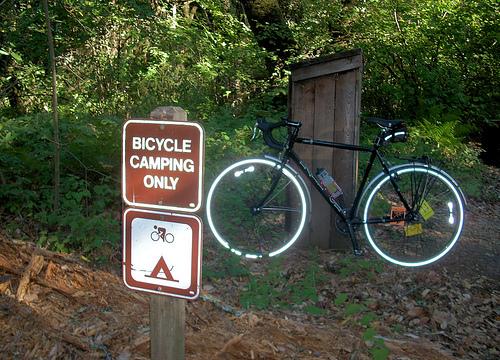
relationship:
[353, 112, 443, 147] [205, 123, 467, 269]
seat on bike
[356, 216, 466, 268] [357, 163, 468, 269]
part of a tire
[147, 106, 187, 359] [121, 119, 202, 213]
wooden post holding signs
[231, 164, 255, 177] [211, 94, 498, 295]
reflector on bike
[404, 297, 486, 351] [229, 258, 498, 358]
leaves on ground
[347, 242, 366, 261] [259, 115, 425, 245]
pedal on bike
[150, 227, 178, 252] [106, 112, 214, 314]
bike on sign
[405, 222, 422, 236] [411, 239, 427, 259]
card in spoke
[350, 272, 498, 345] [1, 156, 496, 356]
dead leaves on ground